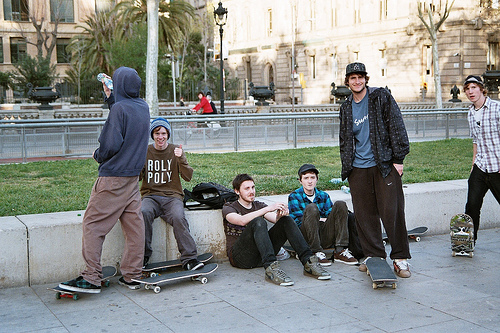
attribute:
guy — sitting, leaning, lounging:
[219, 172, 328, 288]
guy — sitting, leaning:
[282, 163, 360, 268]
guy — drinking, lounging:
[66, 53, 161, 287]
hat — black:
[298, 164, 321, 173]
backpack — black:
[184, 171, 234, 205]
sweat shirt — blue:
[92, 67, 151, 178]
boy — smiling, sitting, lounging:
[149, 112, 207, 267]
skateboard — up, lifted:
[438, 212, 484, 261]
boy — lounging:
[446, 75, 500, 245]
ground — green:
[1, 130, 500, 217]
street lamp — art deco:
[202, 1, 245, 132]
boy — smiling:
[323, 61, 425, 285]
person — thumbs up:
[117, 110, 222, 271]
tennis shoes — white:
[260, 261, 332, 287]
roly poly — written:
[144, 155, 175, 189]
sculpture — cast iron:
[21, 78, 75, 117]